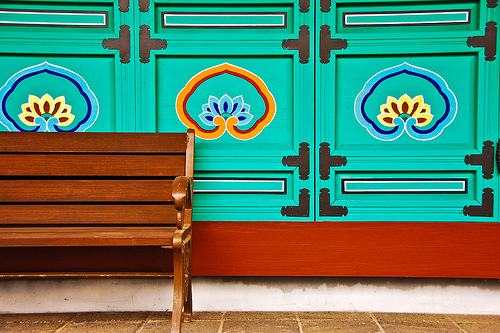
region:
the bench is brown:
[6, 110, 203, 295]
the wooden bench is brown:
[16, 114, 237, 306]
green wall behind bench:
[6, 6, 471, 209]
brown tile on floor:
[336, 306, 498, 332]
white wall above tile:
[342, 276, 489, 310]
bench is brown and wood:
[1, 134, 200, 273]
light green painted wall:
[145, 15, 310, 177]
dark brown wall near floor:
[218, 212, 485, 293]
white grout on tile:
[164, 296, 396, 331]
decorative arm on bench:
[152, 171, 204, 257]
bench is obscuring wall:
[0, 128, 210, 301]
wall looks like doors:
[77, 10, 499, 232]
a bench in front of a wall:
[10, 133, 255, 292]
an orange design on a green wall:
[163, 50, 285, 152]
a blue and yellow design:
[342, 55, 465, 156]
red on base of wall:
[198, 208, 419, 263]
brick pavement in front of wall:
[215, 293, 380, 330]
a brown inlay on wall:
[266, 23, 372, 79]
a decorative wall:
[199, 28, 470, 180]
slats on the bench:
[17, 133, 159, 183]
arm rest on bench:
[160, 166, 217, 314]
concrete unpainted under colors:
[238, 277, 364, 311]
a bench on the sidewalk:
[30, 28, 310, 331]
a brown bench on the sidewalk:
[14, 68, 258, 326]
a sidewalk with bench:
[16, 75, 335, 323]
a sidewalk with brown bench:
[11, 76, 371, 325]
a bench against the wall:
[32, 87, 311, 328]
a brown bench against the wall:
[4, 71, 308, 330]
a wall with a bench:
[7, 61, 344, 330]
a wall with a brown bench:
[32, 72, 305, 332]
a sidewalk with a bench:
[26, 93, 311, 328]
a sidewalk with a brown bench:
[19, 112, 277, 329]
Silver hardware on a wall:
[273, 26, 315, 71]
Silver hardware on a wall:
[466, 136, 495, 178]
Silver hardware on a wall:
[316, 188, 352, 226]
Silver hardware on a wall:
[83, 12, 133, 72]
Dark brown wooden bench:
[16, 110, 203, 328]